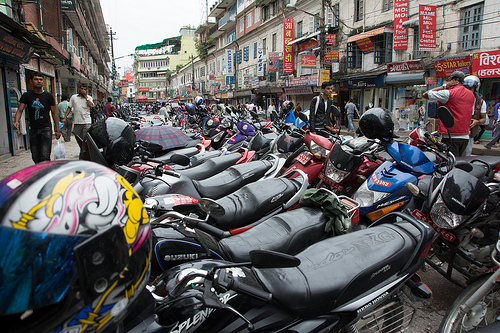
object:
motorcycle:
[115, 151, 308, 200]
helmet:
[0, 158, 163, 333]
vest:
[438, 83, 474, 136]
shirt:
[68, 94, 95, 125]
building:
[132, 22, 213, 103]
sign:
[418, 5, 437, 51]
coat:
[310, 93, 334, 132]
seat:
[172, 151, 242, 180]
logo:
[164, 253, 200, 262]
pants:
[26, 126, 54, 165]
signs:
[354, 36, 376, 56]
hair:
[30, 71, 45, 79]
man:
[422, 69, 475, 157]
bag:
[48, 137, 79, 161]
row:
[110, 113, 498, 333]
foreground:
[0, 123, 236, 331]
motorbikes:
[3, 169, 489, 333]